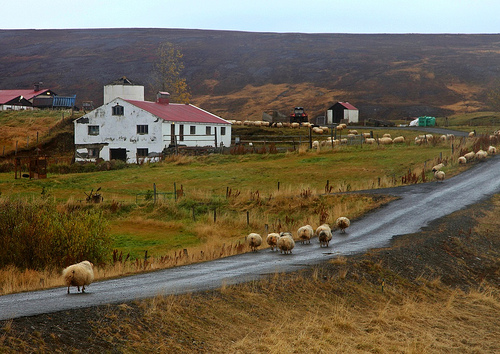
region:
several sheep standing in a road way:
[215, 203, 370, 269]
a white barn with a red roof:
[70, 87, 242, 180]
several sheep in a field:
[294, 128, 444, 151]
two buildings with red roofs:
[0, 72, 64, 128]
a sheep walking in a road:
[48, 241, 128, 313]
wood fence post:
[152, 201, 268, 231]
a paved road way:
[123, 196, 415, 316]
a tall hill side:
[90, 24, 446, 79]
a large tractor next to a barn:
[286, 96, 313, 130]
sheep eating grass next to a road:
[431, 133, 494, 195]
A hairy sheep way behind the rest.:
[60, 258, 95, 293]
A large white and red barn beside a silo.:
[71, 91, 233, 166]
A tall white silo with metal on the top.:
[103, 76, 145, 100]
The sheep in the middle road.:
[241, 215, 352, 262]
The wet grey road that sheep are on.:
[2, 150, 499, 325]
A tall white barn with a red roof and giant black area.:
[325, 98, 360, 124]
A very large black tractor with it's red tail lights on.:
[288, 104, 308, 122]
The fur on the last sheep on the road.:
[59, 258, 94, 285]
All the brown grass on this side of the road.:
[124, 270, 497, 349]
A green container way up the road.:
[416, 114, 433, 125]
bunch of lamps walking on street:
[216, 188, 365, 266]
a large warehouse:
[59, 72, 246, 179]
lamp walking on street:
[50, 250, 110, 306]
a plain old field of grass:
[44, 164, 318, 225]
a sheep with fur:
[59, 258, 104, 295]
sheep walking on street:
[29, 164, 368, 302]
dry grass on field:
[264, 295, 496, 345]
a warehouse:
[319, 100, 370, 128]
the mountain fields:
[5, 19, 498, 102]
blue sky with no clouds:
[36, 0, 493, 32]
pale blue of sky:
[1, 1, 498, 33]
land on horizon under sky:
[3, 29, 495, 98]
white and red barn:
[77, 100, 229, 164]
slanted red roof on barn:
[127, 100, 225, 123]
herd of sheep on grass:
[304, 123, 452, 153]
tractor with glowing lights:
[290, 105, 309, 125]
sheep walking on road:
[62, 215, 349, 294]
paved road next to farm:
[2, 163, 497, 320]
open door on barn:
[109, 147, 128, 162]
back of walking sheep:
[64, 265, 86, 284]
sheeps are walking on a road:
[26, 186, 431, 303]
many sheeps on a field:
[10, 56, 499, 324]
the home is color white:
[65, 73, 239, 167]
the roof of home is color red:
[115, 90, 232, 128]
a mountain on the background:
[6, 20, 493, 172]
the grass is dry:
[163, 260, 492, 352]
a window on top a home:
[91, 93, 143, 120]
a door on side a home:
[160, 118, 234, 146]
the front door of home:
[97, 139, 136, 164]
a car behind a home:
[83, 95, 318, 137]